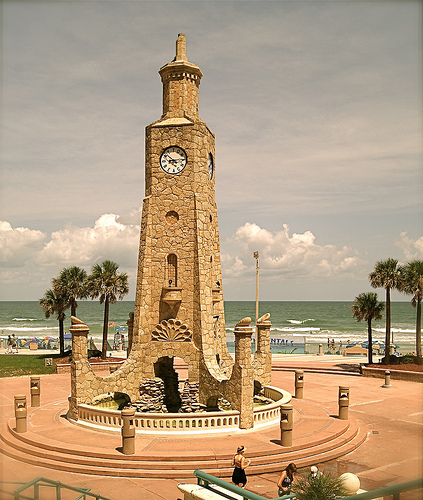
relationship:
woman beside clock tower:
[231, 443, 250, 491] [64, 32, 274, 433]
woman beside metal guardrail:
[276, 459, 297, 492] [194, 464, 300, 498]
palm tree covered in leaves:
[35, 264, 87, 359] [61, 269, 80, 285]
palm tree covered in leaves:
[82, 258, 129, 359] [61, 269, 80, 285]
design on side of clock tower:
[148, 316, 190, 342] [68, 32, 275, 433]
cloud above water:
[221, 215, 363, 280] [0, 290, 418, 354]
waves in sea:
[281, 295, 333, 343] [1, 300, 421, 339]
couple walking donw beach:
[5, 333, 18, 353] [1, 333, 421, 361]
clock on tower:
[151, 140, 201, 184] [62, 30, 287, 480]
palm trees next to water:
[347, 258, 422, 370] [1, 300, 422, 341]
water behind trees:
[233, 296, 378, 324] [357, 254, 420, 357]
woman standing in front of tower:
[276, 461, 296, 496] [94, 26, 245, 401]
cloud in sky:
[0, 207, 422, 299] [7, 11, 421, 241]